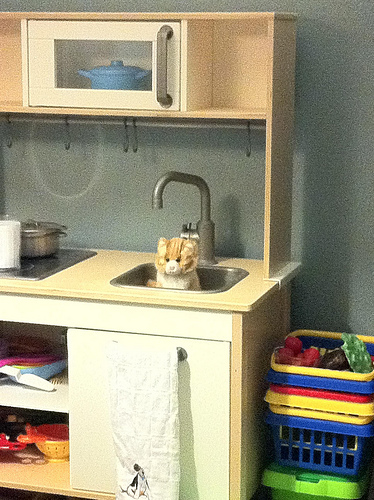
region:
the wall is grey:
[293, 138, 363, 276]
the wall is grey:
[325, 245, 338, 271]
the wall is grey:
[309, 189, 329, 341]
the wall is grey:
[307, 206, 321, 269]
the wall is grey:
[350, 156, 361, 271]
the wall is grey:
[308, 184, 359, 307]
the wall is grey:
[337, 195, 360, 288]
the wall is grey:
[324, 126, 368, 277]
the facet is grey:
[148, 161, 230, 243]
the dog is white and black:
[122, 454, 168, 497]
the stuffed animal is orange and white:
[146, 227, 215, 283]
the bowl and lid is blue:
[72, 51, 155, 91]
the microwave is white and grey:
[13, 6, 203, 124]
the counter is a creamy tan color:
[69, 231, 257, 314]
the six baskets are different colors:
[279, 305, 365, 463]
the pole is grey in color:
[147, 119, 238, 133]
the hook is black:
[59, 114, 81, 154]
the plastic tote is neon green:
[256, 458, 356, 496]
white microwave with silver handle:
[23, 18, 179, 116]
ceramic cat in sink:
[148, 231, 203, 290]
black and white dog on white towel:
[123, 460, 155, 496]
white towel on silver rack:
[106, 335, 190, 361]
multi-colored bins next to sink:
[268, 318, 372, 497]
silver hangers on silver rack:
[1, 113, 269, 156]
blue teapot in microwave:
[77, 60, 152, 95]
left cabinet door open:
[2, 322, 83, 490]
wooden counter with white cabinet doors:
[0, 290, 261, 497]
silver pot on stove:
[21, 214, 68, 257]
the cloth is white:
[103, 336, 179, 492]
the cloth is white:
[129, 376, 223, 495]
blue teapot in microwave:
[78, 63, 145, 85]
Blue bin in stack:
[280, 429, 347, 458]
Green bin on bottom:
[281, 474, 324, 499]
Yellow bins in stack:
[298, 402, 330, 416]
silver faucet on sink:
[141, 162, 182, 217]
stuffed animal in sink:
[141, 233, 215, 306]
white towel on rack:
[114, 345, 183, 428]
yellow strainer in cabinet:
[35, 441, 68, 467]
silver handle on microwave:
[149, 30, 181, 116]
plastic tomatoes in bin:
[284, 337, 305, 359]